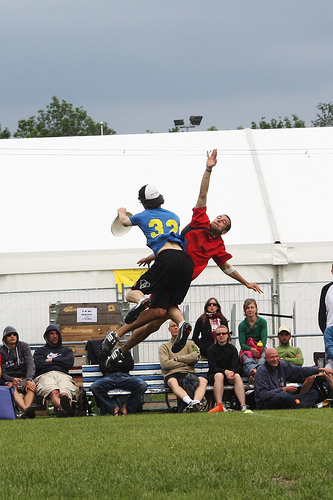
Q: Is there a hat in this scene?
A: Yes, there is a hat.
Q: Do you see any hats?
A: Yes, there is a hat.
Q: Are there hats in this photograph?
A: Yes, there is a hat.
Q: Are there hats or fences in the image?
A: Yes, there is a hat.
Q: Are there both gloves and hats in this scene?
A: No, there is a hat but no gloves.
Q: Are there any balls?
A: No, there are no balls.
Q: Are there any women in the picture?
A: Yes, there is a woman.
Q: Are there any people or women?
A: Yes, there is a woman.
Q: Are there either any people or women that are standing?
A: Yes, the woman is standing.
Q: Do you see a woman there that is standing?
A: Yes, there is a woman that is standing.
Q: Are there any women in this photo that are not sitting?
A: Yes, there is a woman that is standing.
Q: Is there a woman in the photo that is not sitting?
A: Yes, there is a woman that is standing.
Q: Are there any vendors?
A: No, there are no vendors.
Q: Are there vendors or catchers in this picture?
A: No, there are no vendors or catchers.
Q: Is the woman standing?
A: Yes, the woman is standing.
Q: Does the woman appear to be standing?
A: Yes, the woman is standing.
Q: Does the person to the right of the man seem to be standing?
A: Yes, the woman is standing.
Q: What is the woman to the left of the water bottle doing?
A: The woman is standing.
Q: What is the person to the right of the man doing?
A: The woman is standing.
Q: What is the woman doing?
A: The woman is standing.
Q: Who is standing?
A: The woman is standing.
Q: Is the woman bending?
A: No, the woman is standing.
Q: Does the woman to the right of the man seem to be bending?
A: No, the woman is standing.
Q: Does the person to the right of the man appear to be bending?
A: No, the woman is standing.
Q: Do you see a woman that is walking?
A: No, there is a woman but she is standing.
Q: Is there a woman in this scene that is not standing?
A: No, there is a woman but she is standing.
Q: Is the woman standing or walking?
A: The woman is standing.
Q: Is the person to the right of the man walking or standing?
A: The woman is standing.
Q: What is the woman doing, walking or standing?
A: The woman is standing.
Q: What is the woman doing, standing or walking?
A: The woman is standing.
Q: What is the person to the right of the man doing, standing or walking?
A: The woman is standing.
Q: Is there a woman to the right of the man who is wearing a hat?
A: Yes, there is a woman to the right of the man.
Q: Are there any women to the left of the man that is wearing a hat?
A: No, the woman is to the right of the man.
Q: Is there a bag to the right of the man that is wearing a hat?
A: No, there is a woman to the right of the man.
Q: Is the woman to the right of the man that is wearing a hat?
A: Yes, the woman is to the right of the man.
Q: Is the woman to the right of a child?
A: No, the woman is to the right of the man.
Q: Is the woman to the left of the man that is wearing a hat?
A: No, the woman is to the right of the man.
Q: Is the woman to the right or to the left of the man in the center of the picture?
A: The woman is to the right of the man.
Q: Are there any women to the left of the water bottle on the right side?
A: Yes, there is a woman to the left of the water bottle.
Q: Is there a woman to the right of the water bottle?
A: No, the woman is to the left of the water bottle.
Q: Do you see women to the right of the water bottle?
A: No, the woman is to the left of the water bottle.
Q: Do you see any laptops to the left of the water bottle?
A: No, there is a woman to the left of the water bottle.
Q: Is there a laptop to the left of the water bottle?
A: No, there is a woman to the left of the water bottle.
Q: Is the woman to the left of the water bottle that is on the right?
A: Yes, the woman is to the left of the water bottle.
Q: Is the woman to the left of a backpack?
A: No, the woman is to the left of the water bottle.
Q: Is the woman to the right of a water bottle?
A: No, the woman is to the left of a water bottle.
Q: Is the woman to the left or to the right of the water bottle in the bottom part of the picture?
A: The woman is to the left of the water bottle.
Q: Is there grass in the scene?
A: Yes, there is grass.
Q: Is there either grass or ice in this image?
A: Yes, there is grass.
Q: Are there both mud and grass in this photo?
A: No, there is grass but no mud.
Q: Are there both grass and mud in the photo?
A: No, there is grass but no mud.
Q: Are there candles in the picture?
A: No, there are no candles.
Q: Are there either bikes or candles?
A: No, there are no candles or bikes.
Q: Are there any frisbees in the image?
A: Yes, there is a frisbee.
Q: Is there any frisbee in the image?
A: Yes, there is a frisbee.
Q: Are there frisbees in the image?
A: Yes, there is a frisbee.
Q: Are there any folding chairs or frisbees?
A: Yes, there is a frisbee.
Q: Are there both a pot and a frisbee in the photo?
A: No, there is a frisbee but no pots.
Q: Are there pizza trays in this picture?
A: No, there are no pizza trays.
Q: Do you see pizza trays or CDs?
A: No, there are no pizza trays or cds.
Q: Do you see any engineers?
A: No, there are no engineers.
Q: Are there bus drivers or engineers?
A: No, there are no engineers or bus drivers.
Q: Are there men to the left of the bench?
A: Yes, there is a man to the left of the bench.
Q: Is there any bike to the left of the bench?
A: No, there is a man to the left of the bench.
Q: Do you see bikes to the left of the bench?
A: No, there is a man to the left of the bench.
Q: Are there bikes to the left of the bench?
A: No, there is a man to the left of the bench.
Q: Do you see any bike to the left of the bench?
A: No, there is a man to the left of the bench.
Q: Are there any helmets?
A: No, there are no helmets.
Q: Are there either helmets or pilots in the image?
A: No, there are no helmets or pilots.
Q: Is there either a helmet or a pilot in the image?
A: No, there are no helmets or pilots.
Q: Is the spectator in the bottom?
A: Yes, the spectator is in the bottom of the image.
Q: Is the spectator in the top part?
A: No, the spectator is in the bottom of the image.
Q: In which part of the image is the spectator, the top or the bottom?
A: The spectator is in the bottom of the image.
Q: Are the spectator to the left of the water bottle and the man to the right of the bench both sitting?
A: Yes, both the spectator and the man are sitting.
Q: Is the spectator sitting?
A: Yes, the spectator is sitting.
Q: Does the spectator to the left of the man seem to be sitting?
A: Yes, the spectator is sitting.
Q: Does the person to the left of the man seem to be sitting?
A: Yes, the spectator is sitting.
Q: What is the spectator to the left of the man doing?
A: The spectator is sitting.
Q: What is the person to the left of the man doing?
A: The spectator is sitting.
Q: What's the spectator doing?
A: The spectator is sitting.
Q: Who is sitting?
A: The spectator is sitting.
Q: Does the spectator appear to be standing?
A: No, the spectator is sitting.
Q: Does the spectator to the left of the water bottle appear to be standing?
A: No, the spectator is sitting.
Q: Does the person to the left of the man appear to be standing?
A: No, the spectator is sitting.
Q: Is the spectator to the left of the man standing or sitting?
A: The spectator is sitting.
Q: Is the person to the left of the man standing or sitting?
A: The spectator is sitting.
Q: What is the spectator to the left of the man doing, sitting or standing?
A: The spectator is sitting.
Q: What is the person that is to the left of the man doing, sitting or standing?
A: The spectator is sitting.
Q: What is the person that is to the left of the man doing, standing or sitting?
A: The spectator is sitting.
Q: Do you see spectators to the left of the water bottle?
A: Yes, there is a spectator to the left of the water bottle.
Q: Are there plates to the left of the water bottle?
A: No, there is a spectator to the left of the water bottle.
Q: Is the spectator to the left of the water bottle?
A: Yes, the spectator is to the left of the water bottle.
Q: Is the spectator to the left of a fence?
A: No, the spectator is to the left of the water bottle.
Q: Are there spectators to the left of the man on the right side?
A: Yes, there is a spectator to the left of the man.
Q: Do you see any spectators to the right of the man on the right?
A: No, the spectator is to the left of the man.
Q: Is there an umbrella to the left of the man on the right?
A: No, there is a spectator to the left of the man.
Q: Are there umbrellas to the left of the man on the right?
A: No, there is a spectator to the left of the man.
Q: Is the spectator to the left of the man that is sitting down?
A: Yes, the spectator is to the left of the man.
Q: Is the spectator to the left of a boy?
A: No, the spectator is to the left of the man.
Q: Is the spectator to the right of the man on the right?
A: No, the spectator is to the left of the man.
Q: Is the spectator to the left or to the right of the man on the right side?
A: The spectator is to the left of the man.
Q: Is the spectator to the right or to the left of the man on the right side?
A: The spectator is to the left of the man.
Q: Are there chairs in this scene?
A: No, there are no chairs.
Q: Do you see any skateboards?
A: No, there are no skateboards.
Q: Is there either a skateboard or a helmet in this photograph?
A: No, there are no skateboards or helmets.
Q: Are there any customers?
A: No, there are no customers.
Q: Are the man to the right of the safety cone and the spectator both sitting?
A: Yes, both the man and the spectator are sitting.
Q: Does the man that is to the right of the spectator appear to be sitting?
A: Yes, the man is sitting.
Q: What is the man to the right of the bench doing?
A: The man is sitting.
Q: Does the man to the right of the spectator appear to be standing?
A: No, the man is sitting.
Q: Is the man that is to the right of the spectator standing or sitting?
A: The man is sitting.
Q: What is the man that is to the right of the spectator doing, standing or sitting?
A: The man is sitting.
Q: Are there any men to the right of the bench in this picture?
A: Yes, there is a man to the right of the bench.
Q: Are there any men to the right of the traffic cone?
A: Yes, there is a man to the right of the traffic cone.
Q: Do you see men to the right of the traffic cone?
A: Yes, there is a man to the right of the traffic cone.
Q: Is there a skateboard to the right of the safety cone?
A: No, there is a man to the right of the safety cone.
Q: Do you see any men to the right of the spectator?
A: Yes, there is a man to the right of the spectator.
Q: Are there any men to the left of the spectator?
A: No, the man is to the right of the spectator.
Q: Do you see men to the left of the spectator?
A: No, the man is to the right of the spectator.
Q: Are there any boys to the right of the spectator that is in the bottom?
A: No, there is a man to the right of the spectator.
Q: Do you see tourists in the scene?
A: No, there are no tourists.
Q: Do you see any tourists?
A: No, there are no tourists.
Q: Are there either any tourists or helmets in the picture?
A: No, there are no tourists or helmets.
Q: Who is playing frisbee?
A: The man is playing frisbee.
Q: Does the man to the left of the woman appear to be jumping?
A: Yes, the man is jumping.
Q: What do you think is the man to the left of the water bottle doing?
A: The man is jumping.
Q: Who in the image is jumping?
A: The man is jumping.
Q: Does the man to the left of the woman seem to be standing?
A: No, the man is jumping.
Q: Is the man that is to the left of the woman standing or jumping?
A: The man is jumping.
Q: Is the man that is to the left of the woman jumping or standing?
A: The man is jumping.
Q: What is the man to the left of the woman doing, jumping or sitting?
A: The man is jumping.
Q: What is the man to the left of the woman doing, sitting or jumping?
A: The man is jumping.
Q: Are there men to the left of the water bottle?
A: Yes, there is a man to the left of the water bottle.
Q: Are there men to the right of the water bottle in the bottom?
A: No, the man is to the left of the water bottle.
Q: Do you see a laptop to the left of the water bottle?
A: No, there is a man to the left of the water bottle.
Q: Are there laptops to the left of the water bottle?
A: No, there is a man to the left of the water bottle.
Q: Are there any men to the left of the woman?
A: Yes, there is a man to the left of the woman.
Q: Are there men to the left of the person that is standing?
A: Yes, there is a man to the left of the woman.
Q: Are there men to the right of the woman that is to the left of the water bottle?
A: No, the man is to the left of the woman.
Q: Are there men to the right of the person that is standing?
A: No, the man is to the left of the woman.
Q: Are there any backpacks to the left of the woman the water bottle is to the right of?
A: No, there is a man to the left of the woman.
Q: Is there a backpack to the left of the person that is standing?
A: No, there is a man to the left of the woman.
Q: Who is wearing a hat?
A: The man is wearing a hat.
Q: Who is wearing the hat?
A: The man is wearing a hat.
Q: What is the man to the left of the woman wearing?
A: The man is wearing a hat.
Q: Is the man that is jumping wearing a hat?
A: Yes, the man is wearing a hat.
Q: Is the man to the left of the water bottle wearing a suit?
A: No, the man is wearing a hat.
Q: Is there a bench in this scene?
A: Yes, there is a bench.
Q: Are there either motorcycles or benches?
A: Yes, there is a bench.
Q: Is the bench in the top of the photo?
A: No, the bench is in the bottom of the image.